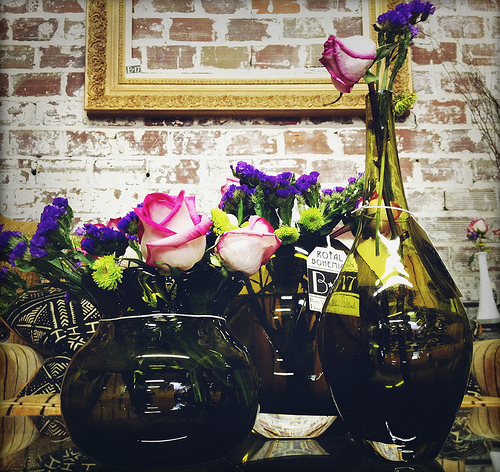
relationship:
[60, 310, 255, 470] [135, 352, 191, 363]
vase showing reflection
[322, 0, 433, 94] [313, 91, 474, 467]
flowers in vase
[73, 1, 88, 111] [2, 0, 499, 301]
edge of wall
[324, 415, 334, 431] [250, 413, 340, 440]
part of a bulb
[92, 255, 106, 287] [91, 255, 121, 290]
part of a flower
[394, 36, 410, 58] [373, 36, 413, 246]
part of a stem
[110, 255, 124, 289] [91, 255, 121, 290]
edge of a flower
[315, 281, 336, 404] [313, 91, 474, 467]
side of a vase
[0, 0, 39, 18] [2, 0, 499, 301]
part of a wall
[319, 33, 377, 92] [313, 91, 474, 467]
rose leaning over vase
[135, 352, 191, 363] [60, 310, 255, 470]
reflection on vase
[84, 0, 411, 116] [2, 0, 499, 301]
frame on wall